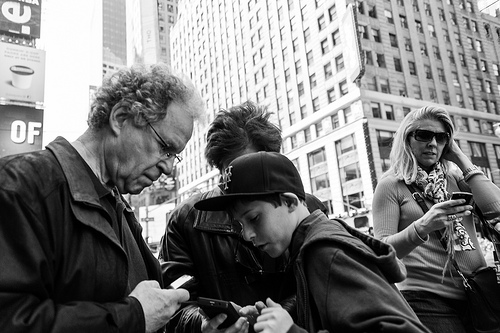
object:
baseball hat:
[193, 150, 306, 211]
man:
[2, 63, 203, 332]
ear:
[109, 100, 134, 136]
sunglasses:
[413, 129, 450, 142]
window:
[334, 132, 358, 159]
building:
[169, 0, 498, 235]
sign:
[336, 2, 365, 84]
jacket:
[0, 136, 166, 330]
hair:
[86, 60, 204, 129]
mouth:
[141, 171, 157, 184]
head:
[87, 64, 202, 199]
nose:
[157, 158, 176, 176]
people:
[368, 103, 499, 332]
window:
[327, 3, 339, 24]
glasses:
[141, 110, 186, 164]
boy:
[191, 148, 433, 332]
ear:
[282, 192, 299, 213]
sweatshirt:
[289, 209, 431, 333]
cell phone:
[449, 191, 472, 204]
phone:
[168, 274, 195, 291]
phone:
[197, 297, 245, 329]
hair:
[377, 105, 457, 184]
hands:
[255, 298, 297, 333]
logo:
[218, 165, 233, 191]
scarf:
[413, 162, 477, 253]